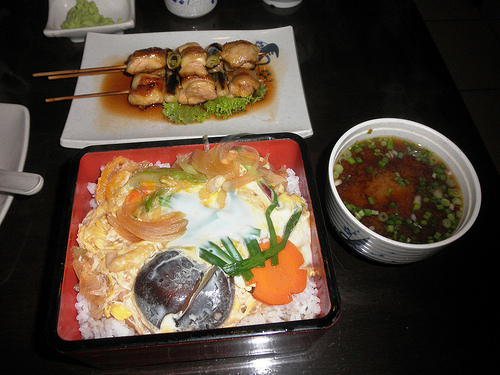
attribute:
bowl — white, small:
[321, 114, 482, 268]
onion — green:
[380, 210, 388, 223]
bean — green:
[265, 200, 282, 269]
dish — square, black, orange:
[33, 132, 340, 372]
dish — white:
[41, 3, 137, 45]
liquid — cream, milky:
[160, 182, 314, 271]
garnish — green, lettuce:
[160, 86, 269, 127]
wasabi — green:
[64, 2, 125, 36]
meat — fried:
[122, 47, 170, 75]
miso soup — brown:
[332, 134, 465, 245]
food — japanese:
[71, 138, 321, 340]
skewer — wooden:
[44, 78, 266, 110]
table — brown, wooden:
[0, 0, 498, 374]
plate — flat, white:
[59, 23, 315, 149]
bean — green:
[199, 248, 236, 276]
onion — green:
[373, 146, 381, 159]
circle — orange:
[241, 235, 310, 306]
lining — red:
[55, 138, 334, 341]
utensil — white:
[2, 168, 45, 201]